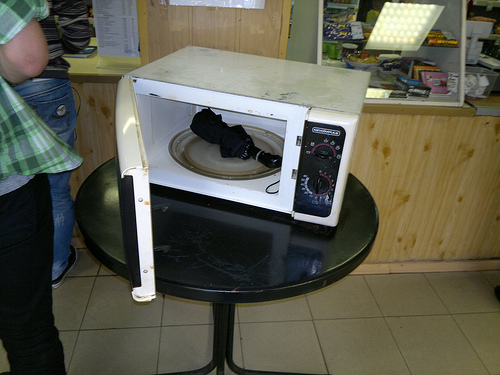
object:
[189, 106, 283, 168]
umbrella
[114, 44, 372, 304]
microwave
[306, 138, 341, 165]
dial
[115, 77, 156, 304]
door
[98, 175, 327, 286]
table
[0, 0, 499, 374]
room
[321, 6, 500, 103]
display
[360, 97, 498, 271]
counter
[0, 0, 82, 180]
shirt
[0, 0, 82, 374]
person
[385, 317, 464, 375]
tile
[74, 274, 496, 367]
floor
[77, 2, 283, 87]
wall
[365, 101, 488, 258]
wood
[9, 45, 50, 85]
elbow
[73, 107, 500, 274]
paneling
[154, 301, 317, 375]
base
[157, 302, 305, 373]
underneath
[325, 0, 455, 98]
food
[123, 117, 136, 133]
light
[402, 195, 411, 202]
knot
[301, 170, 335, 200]
dial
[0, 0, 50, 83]
arm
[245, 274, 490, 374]
section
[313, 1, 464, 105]
glass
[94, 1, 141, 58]
menu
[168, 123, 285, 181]
microwave tray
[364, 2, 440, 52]
lights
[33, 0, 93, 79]
shirt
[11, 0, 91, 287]
person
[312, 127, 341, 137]
branding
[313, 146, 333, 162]
buttons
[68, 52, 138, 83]
board